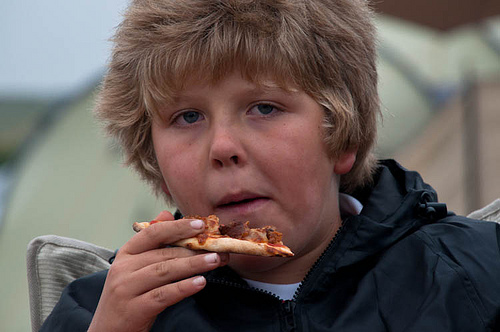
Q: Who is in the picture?
A: Little boy.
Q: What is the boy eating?
A: Pizza.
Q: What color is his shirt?
A: White.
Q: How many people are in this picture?
A: One.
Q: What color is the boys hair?
A: Blonde.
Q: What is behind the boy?
A: Pillow.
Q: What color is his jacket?
A: Black.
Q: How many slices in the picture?
A: One.